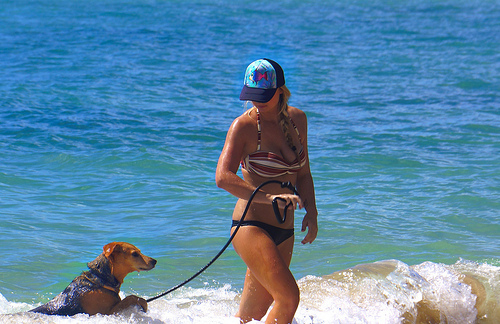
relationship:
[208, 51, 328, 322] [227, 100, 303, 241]
woman in bikini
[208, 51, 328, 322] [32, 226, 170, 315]
woman walking dog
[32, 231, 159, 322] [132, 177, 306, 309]
dog on leash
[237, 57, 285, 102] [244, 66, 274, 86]
cap with fish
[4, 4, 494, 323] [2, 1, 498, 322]
body of water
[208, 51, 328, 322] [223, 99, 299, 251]
woman wearing bikini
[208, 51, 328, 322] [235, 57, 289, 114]
woman wearing cap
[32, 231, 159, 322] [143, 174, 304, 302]
dog on leash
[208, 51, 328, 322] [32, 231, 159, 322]
woman walking dog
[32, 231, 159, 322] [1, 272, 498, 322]
dog on beach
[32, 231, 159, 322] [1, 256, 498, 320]
dog in waves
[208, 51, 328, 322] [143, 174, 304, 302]
woman holding leash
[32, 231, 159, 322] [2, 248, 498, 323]
dog walking on surf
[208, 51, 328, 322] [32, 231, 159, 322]
woman looking at dog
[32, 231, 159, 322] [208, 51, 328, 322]
dog with woman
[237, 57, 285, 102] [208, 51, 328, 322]
cap on woman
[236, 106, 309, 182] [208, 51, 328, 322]
top on woman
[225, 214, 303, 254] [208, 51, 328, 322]
bottom on woman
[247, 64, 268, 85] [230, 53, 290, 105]
image on hat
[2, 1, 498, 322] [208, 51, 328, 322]
water behind woman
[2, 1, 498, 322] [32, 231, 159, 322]
water behind dog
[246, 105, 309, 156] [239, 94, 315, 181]
straps on top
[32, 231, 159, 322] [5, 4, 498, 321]
dog in ocean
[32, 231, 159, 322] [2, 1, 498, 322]
dog swimming in water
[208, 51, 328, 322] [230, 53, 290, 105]
woman wearing hat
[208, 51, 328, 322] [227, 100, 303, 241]
woman wearing bikini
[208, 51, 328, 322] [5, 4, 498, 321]
woman in ocean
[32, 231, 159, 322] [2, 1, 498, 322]
dog in water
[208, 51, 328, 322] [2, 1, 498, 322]
woman in water